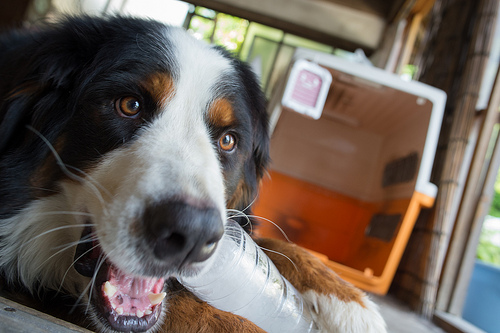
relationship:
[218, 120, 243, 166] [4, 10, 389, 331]
eye on dog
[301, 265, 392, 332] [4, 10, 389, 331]
paw of a dog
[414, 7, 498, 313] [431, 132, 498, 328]
curtain of a window